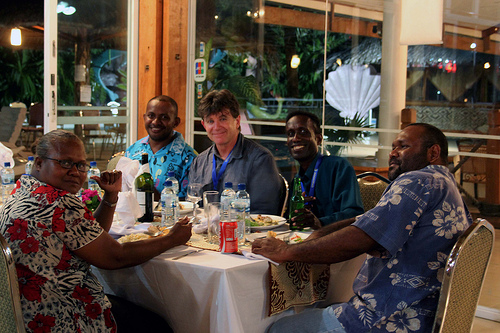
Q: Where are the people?
A: In a restaurant.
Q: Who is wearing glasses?
A: The woman.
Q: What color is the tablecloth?
A: White.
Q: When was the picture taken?
A: During the night.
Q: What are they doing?
A: Eating.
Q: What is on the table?
A: Dinner.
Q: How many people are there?
A: 5.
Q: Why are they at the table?
A: They're eating.